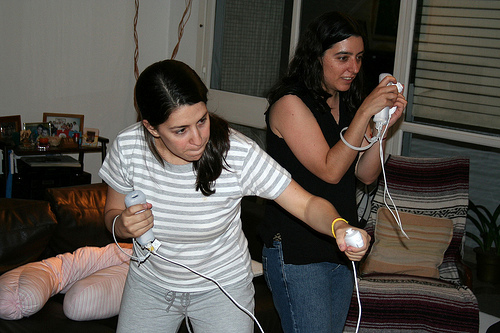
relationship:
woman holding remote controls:
[104, 27, 384, 321] [92, 170, 391, 325]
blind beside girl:
[410, 3, 498, 131] [268, 14, 397, 324]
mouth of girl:
[338, 75, 356, 84] [268, 14, 397, 324]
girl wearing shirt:
[268, 14, 397, 324] [256, 83, 361, 270]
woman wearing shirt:
[104, 27, 372, 332] [105, 117, 285, 291]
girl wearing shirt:
[268, 14, 397, 324] [271, 92, 369, 261]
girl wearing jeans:
[268, 14, 397, 324] [261, 230, 359, 332]